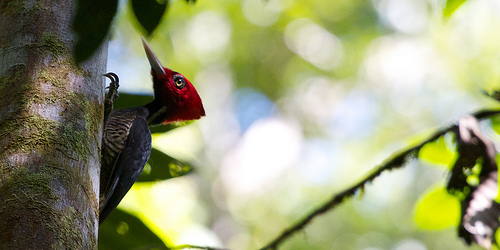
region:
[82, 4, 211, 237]
bird on side of tree trunk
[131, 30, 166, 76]
bird beak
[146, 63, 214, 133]
red feathers on bird's head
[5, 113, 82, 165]
green patch on tree trunk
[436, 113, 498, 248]
leaf on plant stem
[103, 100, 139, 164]
striped pattern on bird chest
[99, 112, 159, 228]
grey and brown bird feather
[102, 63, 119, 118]
bird claw on tree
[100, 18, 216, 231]
bird on side of tree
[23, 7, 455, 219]
a woodpecker on a tree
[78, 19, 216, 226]
a red woodpecker on a tree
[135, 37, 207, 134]
the woodpecker's head is red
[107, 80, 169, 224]
the bird's body is black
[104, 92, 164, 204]
this bird has black feathers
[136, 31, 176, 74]
the bird's beak is sharp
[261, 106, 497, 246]
a tree limb with leaves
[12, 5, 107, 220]
a treetrunk in the shot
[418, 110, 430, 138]
part of a twig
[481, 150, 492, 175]
part of a leaf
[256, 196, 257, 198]
edge of a tree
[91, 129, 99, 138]
part of a stem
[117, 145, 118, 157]
part of a bird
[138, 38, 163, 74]
the pointy beak of a bird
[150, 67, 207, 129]
the red head of a bird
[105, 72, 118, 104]
the long claws of a bird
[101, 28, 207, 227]
a brightly colored woodpecker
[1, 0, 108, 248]
a moss covered tree trunk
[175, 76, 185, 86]
the yellow left eye of a woodpecker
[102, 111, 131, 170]
the striped underbelly of a woodpecker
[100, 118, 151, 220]
gray feathers on the back of a woodpecker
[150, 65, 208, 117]
bright red feathers on a woodpecker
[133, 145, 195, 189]
a partially caterpillar eaten leaf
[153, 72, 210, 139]
red face on bird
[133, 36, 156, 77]
long gray beak on bird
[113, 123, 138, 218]
feather is gray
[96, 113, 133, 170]
body is striped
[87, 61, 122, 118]
feet on the tree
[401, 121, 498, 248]
flowers on the branch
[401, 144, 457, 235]
yellow flowers on the branch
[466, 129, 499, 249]
white leaves on the branch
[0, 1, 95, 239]
bird on the tree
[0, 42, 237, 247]
woodpecker and the tree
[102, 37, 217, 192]
a bird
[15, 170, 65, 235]
grass on the tree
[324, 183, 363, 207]
a twig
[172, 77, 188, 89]
eye of the bird